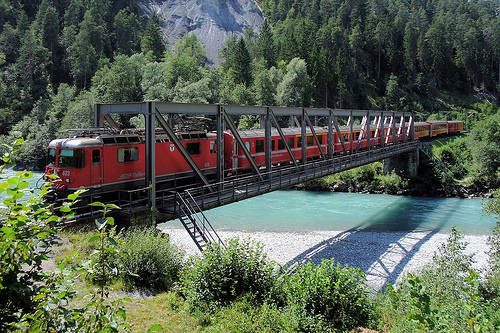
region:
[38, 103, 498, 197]
this is a red train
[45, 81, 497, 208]
the train is on a steel bridge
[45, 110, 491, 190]
the train is crossing a bridge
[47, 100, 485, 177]
the train is crossing over a river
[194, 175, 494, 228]
a fresh water river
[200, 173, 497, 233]
the river is a bluish-green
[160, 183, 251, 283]
a staircase that leads up to the bridge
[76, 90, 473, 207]
the bridge has steel beams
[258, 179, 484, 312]
this is the shadow of the bridge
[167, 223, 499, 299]
the shore is white and rocky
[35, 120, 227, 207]
red car of a train on a bridge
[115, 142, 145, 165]
large window on a red train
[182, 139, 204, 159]
large window on a red train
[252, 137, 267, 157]
large window on a red train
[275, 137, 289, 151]
large window on a red train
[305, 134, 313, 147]
large window on a red train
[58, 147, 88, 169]
large window on a red train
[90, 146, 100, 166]
large window on a red train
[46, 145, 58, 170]
large window on a red train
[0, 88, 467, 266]
train traveling over a metal bridge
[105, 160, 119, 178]
the train is red in color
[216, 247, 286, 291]
this is a tree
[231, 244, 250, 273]
the tree is green in color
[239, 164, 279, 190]
this is the railway line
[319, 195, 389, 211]
this is a stream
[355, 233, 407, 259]
this is a small rocks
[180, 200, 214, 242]
this is a stair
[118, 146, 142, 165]
this is the window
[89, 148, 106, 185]
this is the door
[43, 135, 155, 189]
this is a train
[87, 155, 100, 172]
the train is red in color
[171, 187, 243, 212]
this is a railway line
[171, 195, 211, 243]
this is a stair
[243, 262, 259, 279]
the leaves are green in color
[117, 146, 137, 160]
this is the window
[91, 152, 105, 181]
this is the door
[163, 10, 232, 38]
this is a hill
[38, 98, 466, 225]
this is a train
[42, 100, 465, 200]
this is a red train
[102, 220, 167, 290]
this is a green bush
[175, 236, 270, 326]
this is a green bush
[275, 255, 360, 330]
this is a green bush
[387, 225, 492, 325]
this is a green bush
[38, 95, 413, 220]
this is a bridge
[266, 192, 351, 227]
this is a body of water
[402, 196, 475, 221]
this is a body of water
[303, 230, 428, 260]
this is a shadow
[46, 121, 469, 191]
train is red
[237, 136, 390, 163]
stripe on the train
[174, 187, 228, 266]
stairs to the train tracks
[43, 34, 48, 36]
A green leaf on a plant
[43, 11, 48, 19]
A green leaf on a plant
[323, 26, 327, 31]
A green leaf on a plant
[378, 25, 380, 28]
A green leaf on a plant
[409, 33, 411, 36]
A green leaf on a plant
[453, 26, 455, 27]
A green leaf on a plant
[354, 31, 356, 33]
A green leaf on a plant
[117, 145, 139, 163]
Window of a train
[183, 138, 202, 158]
Window of a train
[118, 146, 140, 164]
Window of a red train